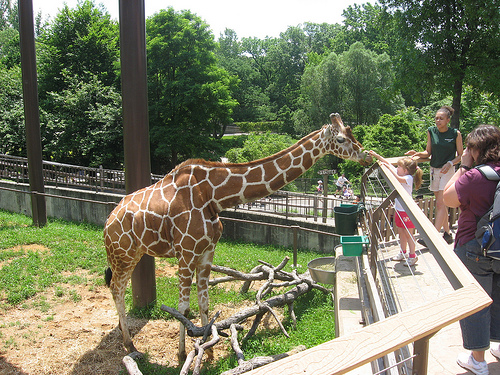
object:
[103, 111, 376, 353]
giraffe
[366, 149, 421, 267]
girl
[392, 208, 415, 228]
red shorts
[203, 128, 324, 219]
long neck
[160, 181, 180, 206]
brown spots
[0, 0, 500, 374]
zoo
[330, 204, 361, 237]
trash cans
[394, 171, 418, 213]
white shirt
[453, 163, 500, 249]
purple shirt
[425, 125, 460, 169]
green shirt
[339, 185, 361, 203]
stroller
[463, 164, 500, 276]
backpack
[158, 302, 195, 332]
branches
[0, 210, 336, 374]
ground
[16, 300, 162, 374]
dirt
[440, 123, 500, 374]
lady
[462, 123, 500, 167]
big hairdo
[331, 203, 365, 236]
feed container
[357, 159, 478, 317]
ledge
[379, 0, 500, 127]
trees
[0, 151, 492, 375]
cage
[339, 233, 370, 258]
buckets